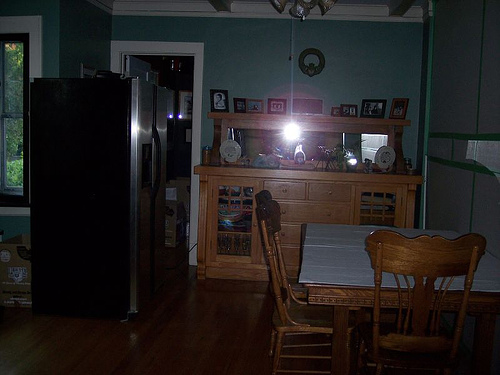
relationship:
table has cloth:
[304, 206, 490, 320] [300, 220, 381, 279]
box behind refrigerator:
[5, 237, 32, 307] [35, 79, 178, 317]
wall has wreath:
[213, 19, 422, 102] [296, 48, 327, 79]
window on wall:
[1, 38, 43, 201] [5, 9, 56, 97]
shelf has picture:
[212, 108, 406, 137] [383, 94, 412, 129]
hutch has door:
[202, 104, 421, 309] [218, 172, 262, 275]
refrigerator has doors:
[35, 79, 178, 317] [126, 87, 171, 332]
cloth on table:
[300, 220, 381, 279] [304, 206, 490, 320]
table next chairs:
[304, 206, 490, 320] [244, 180, 305, 345]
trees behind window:
[5, 53, 23, 174] [1, 24, 42, 216]